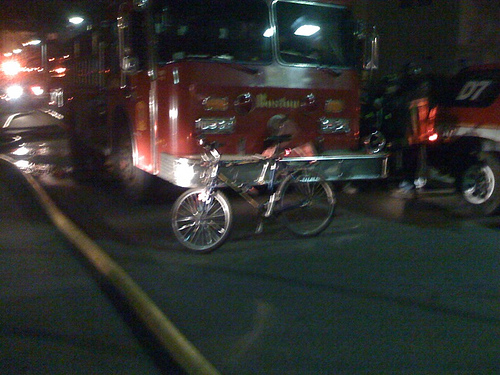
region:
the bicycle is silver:
[122, 96, 384, 353]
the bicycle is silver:
[130, 105, 290, 226]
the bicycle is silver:
[207, 139, 405, 284]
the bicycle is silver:
[178, 138, 325, 268]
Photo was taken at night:
[6, 4, 486, 367]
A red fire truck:
[53, 1, 390, 208]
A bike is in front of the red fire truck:
[148, 123, 356, 261]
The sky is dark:
[5, 0, 102, 26]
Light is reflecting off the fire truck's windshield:
[285, 10, 321, 45]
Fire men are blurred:
[371, 50, 442, 195]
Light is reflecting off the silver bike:
[162, 125, 252, 250]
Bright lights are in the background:
[0, 46, 50, 101]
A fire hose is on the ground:
[20, 171, 228, 372]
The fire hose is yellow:
[43, 183, 218, 369]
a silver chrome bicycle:
[167, 124, 339, 254]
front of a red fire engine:
[65, 2, 378, 195]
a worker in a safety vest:
[396, 79, 440, 196]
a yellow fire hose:
[0, 144, 227, 373]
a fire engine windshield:
[173, 2, 353, 69]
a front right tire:
[106, 136, 145, 198]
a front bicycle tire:
[168, 185, 231, 255]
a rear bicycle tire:
[272, 166, 337, 238]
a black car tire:
[453, 147, 498, 221]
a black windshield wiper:
[185, 49, 261, 79]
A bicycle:
[175, 135, 453, 370]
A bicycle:
[168, 151, 272, 266]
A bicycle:
[125, 89, 322, 371]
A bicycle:
[193, 139, 285, 362]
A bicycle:
[154, 108, 307, 264]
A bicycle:
[174, 93, 331, 216]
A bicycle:
[196, 150, 368, 262]